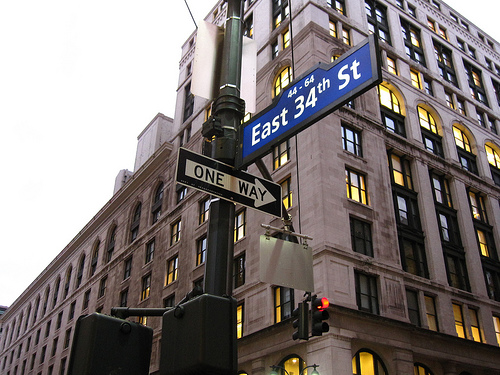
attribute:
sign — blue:
[246, 46, 386, 147]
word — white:
[246, 109, 289, 144]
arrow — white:
[176, 158, 284, 212]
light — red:
[310, 287, 331, 311]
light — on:
[286, 352, 305, 367]